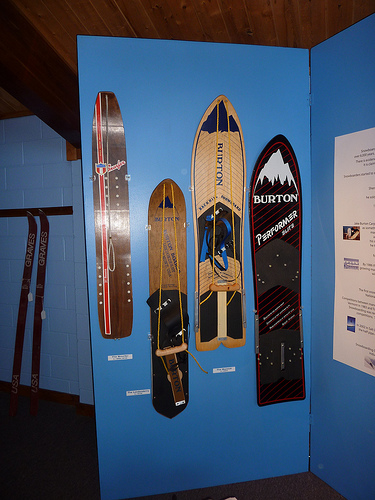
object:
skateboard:
[91, 88, 137, 342]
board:
[75, 31, 312, 500]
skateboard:
[146, 175, 192, 420]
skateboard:
[189, 90, 248, 353]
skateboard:
[247, 133, 308, 408]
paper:
[332, 124, 375, 377]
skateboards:
[91, 89, 136, 340]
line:
[95, 91, 113, 336]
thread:
[157, 182, 167, 349]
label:
[107, 353, 133, 361]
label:
[126, 388, 151, 396]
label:
[213, 365, 236, 374]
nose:
[207, 91, 235, 107]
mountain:
[254, 147, 303, 196]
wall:
[1, 115, 96, 407]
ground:
[0, 381, 344, 500]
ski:
[0, 204, 73, 419]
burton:
[254, 193, 299, 204]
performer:
[255, 210, 301, 247]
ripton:
[216, 142, 224, 186]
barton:
[155, 216, 180, 223]